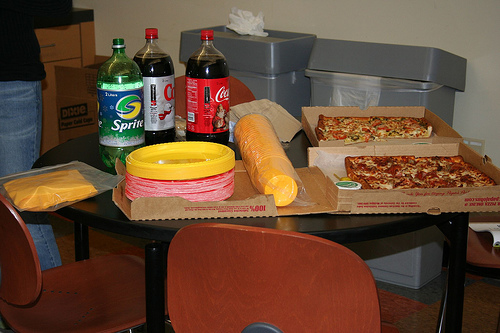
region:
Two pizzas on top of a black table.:
[13, 114, 499, 331]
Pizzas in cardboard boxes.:
[109, 98, 499, 220]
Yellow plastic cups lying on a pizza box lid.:
[231, 111, 306, 206]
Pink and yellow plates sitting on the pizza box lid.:
[121, 140, 233, 205]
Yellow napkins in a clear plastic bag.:
[2, 157, 124, 212]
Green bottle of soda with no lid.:
[97, 35, 145, 162]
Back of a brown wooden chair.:
[162, 220, 379, 330]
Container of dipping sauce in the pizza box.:
[330, 175, 360, 190]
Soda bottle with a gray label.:
[130, 25, 171, 140]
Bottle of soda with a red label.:
[184, 27, 229, 156]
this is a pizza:
[370, 151, 453, 184]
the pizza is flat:
[368, 150, 458, 185]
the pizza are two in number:
[373, 110, 437, 185]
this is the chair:
[205, 234, 360, 320]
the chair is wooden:
[205, 240, 306, 306]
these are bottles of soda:
[99, 30, 231, 134]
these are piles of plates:
[125, 141, 230, 192]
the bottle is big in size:
[187, 22, 229, 129]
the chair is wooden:
[231, 240, 345, 325]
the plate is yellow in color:
[170, 143, 213, 164]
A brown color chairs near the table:
[4, 233, 396, 330]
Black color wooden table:
[316, 218, 400, 232]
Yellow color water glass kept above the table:
[246, 115, 287, 197]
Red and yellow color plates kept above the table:
[123, 150, 234, 198]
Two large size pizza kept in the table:
[322, 105, 491, 202]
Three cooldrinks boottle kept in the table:
[101, 39, 233, 101]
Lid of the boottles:
[144, 28, 224, 40]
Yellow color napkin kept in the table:
[23, 170, 88, 205]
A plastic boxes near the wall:
[273, 35, 454, 67]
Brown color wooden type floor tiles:
[396, 289, 431, 316]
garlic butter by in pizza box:
[334, 177, 360, 189]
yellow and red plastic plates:
[121, 140, 236, 202]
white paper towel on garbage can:
[224, 5, 271, 41]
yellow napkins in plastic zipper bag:
[7, 161, 98, 216]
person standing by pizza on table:
[0, 0, 76, 277]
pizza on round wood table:
[347, 149, 495, 203]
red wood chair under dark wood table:
[167, 221, 363, 330]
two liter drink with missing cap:
[98, 37, 145, 168]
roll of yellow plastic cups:
[237, 112, 304, 203]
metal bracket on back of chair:
[242, 324, 281, 331]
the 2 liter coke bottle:
[182, 30, 229, 143]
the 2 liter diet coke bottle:
[131, 27, 176, 144]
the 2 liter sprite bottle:
[96, 37, 144, 169]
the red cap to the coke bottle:
[200, 28, 213, 37]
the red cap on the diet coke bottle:
[144, 27, 157, 36]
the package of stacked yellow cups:
[235, 111, 313, 204]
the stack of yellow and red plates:
[122, 139, 235, 204]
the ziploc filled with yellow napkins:
[0, 159, 125, 214]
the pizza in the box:
[316, 111, 431, 143]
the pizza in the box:
[344, 155, 496, 191]